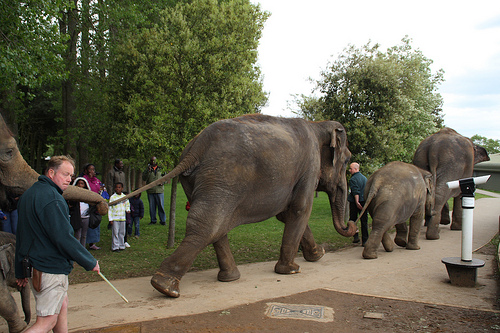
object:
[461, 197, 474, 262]
pole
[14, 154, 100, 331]
man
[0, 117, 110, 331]
elephant